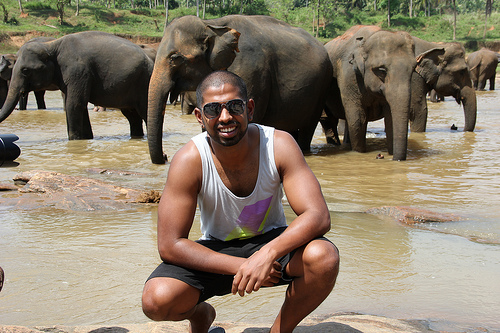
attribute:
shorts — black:
[136, 230, 346, 292]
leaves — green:
[391, 13, 415, 25]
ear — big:
[199, 23, 241, 72]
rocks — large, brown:
[358, 194, 498, 249]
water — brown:
[367, 148, 460, 187]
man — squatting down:
[104, 66, 338, 316]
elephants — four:
[7, 9, 487, 168]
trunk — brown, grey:
[134, 96, 184, 158]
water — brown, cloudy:
[5, 95, 498, 307]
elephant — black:
[1, 29, 153, 141]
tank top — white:
[184, 124, 299, 265]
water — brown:
[0, 85, 500, 330]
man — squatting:
[155, 61, 338, 312]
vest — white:
[150, 135, 341, 259]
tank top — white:
[175, 135, 255, 242]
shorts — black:
[141, 223, 292, 295]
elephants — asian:
[51, 15, 437, 152]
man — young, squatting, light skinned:
[141, 69, 340, 330]